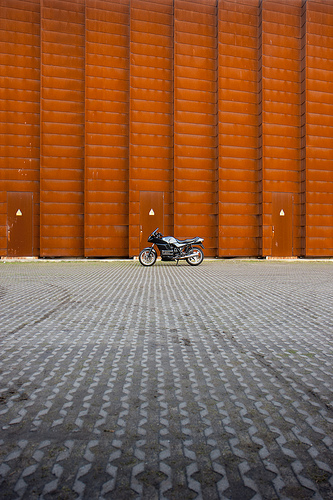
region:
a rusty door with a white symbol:
[265, 187, 294, 257]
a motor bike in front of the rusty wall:
[135, 227, 204, 265]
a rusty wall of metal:
[5, 1, 328, 257]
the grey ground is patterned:
[2, 263, 330, 498]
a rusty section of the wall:
[127, 0, 177, 255]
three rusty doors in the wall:
[5, 186, 300, 260]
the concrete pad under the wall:
[1, 253, 331, 264]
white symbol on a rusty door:
[147, 206, 154, 215]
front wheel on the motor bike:
[136, 246, 157, 266]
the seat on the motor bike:
[171, 234, 202, 244]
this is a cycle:
[139, 235, 179, 254]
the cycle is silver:
[137, 223, 237, 280]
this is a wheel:
[120, 229, 220, 285]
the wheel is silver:
[139, 240, 171, 288]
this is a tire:
[110, 251, 192, 300]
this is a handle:
[152, 225, 162, 236]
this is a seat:
[151, 236, 192, 249]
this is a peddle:
[162, 253, 197, 273]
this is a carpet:
[128, 324, 225, 404]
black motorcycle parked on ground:
[131, 230, 213, 269]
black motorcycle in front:
[137, 227, 212, 276]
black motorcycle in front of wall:
[125, 227, 216, 272]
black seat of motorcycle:
[175, 236, 196, 243]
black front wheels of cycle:
[139, 248, 154, 267]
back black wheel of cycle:
[182, 247, 206, 266]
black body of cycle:
[160, 241, 176, 262]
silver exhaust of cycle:
[178, 254, 196, 259]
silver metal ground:
[10, 282, 199, 486]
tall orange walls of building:
[15, 0, 118, 257]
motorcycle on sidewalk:
[134, 219, 213, 272]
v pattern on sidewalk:
[68, 369, 246, 494]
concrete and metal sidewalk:
[1, 261, 331, 497]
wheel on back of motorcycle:
[181, 245, 206, 267]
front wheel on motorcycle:
[134, 246, 159, 266]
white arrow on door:
[145, 202, 159, 220]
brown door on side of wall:
[135, 186, 170, 258]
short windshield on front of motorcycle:
[147, 224, 161, 239]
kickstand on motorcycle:
[172, 258, 181, 267]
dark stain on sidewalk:
[168, 331, 200, 356]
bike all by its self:
[55, 135, 254, 291]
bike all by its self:
[124, 102, 206, 396]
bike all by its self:
[127, 188, 277, 416]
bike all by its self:
[132, 188, 257, 423]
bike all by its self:
[95, 176, 263, 414]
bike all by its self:
[117, 177, 266, 399]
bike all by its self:
[117, 190, 253, 430]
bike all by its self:
[112, 195, 254, 452]